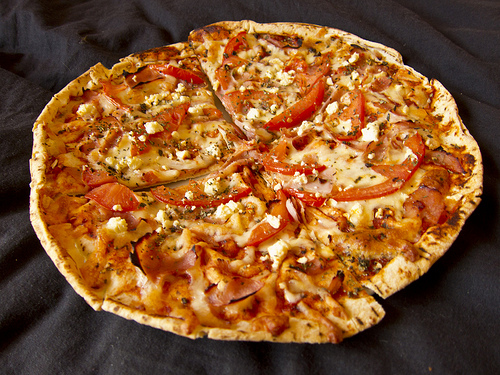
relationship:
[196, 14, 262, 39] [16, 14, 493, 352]
edge of pizza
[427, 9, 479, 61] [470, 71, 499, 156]
part of a cloth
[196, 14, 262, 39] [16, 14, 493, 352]
edge of a pizza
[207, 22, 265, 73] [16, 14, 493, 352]
part of a pizza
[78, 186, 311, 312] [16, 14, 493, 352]
side of a pizza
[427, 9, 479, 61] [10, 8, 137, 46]
part of a sheet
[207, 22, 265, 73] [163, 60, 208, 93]
part of a tomato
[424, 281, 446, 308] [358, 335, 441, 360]
part of a duvet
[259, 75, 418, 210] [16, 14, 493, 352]
tomatoes on pizza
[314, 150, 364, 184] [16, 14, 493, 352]
cheese on pizza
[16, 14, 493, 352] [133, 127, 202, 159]
pizza has black and green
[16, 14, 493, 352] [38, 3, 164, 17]
pizza on top of blanket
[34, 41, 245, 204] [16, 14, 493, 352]
slices of a pizza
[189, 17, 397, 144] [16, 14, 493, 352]
slice of pizza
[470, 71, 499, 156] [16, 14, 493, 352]
cloth framing homemade pizza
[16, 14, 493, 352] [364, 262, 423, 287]
pizza on a pita type crust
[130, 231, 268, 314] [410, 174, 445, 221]
prosciutto or other type of ham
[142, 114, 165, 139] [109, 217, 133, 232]
feta or goat cheese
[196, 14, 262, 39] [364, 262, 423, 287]
edge of crust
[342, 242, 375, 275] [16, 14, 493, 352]
oregano atop of pizza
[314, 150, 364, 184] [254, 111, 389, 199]
cheese beneath toppings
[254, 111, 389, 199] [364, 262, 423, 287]
toppings at edges of crust